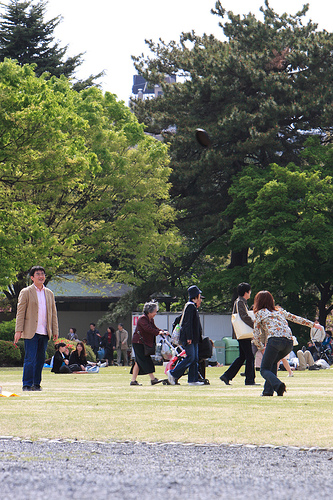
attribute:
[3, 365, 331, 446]
field — grass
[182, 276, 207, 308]
hat — blue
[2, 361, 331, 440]
grass — green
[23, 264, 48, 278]
hair — short, black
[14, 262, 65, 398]
man — standing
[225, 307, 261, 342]
bag — white, large, square, big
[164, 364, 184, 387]
shoe — white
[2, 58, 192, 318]
tree — green, large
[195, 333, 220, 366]
purse — black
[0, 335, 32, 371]
rose bush — large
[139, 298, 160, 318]
hair — grey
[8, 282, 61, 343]
jacket — tan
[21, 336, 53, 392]
pants — blue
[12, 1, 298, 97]
sky — light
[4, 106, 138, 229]
leaves — green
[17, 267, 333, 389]
people — looking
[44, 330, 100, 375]
people — sitting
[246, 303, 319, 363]
shirt — long sleeved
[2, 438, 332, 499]
ground — gravel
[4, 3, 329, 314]
trees — green, tall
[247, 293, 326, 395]
woman — rollerskating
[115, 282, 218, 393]
adults — walking